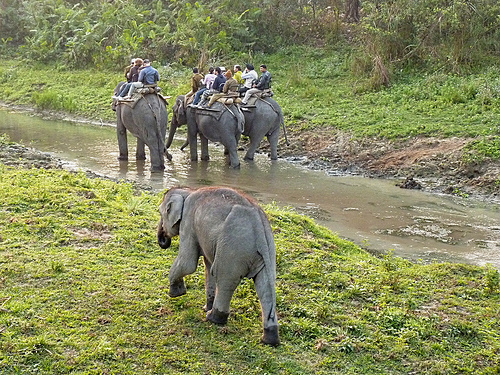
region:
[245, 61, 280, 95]
man looking at other person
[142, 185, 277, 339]
elephant following the men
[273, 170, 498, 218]
the water is murky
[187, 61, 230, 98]
four men riding the elephant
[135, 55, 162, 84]
man has on blue jacket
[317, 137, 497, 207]
rocks on the side of water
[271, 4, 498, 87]
dense bushes in background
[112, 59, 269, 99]
ten men riding three elephants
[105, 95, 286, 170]
three elephants carrying men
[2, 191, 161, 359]
the grass is patchy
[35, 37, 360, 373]
A group of people riding elephants and one lone elephant.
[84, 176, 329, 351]
An elephant by itself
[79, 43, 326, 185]
Three elephants being ridden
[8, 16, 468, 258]
Elephants being ridden down a small stream.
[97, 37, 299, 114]
11 people riding elephants.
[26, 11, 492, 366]
A lush looking landscape with a small river.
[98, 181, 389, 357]
An elephant walking through grass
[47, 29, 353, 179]
Elephants walking on a small river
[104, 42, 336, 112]
Groups of people riding elephants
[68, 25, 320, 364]
Four elephants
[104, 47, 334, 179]
tourists riding elephants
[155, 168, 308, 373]
a baby elephant following behind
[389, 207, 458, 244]
a patch of sand and rocks in the stream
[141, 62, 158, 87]
a man wearing a denim shirt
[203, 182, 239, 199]
fine brown hair on the back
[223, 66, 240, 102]
a man wearing a brown knit cap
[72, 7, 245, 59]
tropical plants next to the stream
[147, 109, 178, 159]
the long gray tail of an elephant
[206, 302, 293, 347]
wet feet on the elephant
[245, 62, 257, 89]
a man wearing a black turban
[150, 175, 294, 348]
a small grey elephant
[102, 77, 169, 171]
a large grey elephant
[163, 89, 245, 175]
a large grey elephant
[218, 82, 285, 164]
a large grey elephant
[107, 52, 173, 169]
people riding on top of an elephant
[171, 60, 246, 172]
people riding on top of an elephant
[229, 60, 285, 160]
people riding on top of an elephant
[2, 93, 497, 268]
a small muddy stream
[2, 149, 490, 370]
a grassy shore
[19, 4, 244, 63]
large green bushes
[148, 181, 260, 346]
this is an elephant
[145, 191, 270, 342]
the elephant is grey in color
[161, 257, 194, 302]
the leg is raised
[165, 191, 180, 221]
the ear is folded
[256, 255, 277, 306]
the tail is long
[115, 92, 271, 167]
the elephants are three in number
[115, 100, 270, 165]
they are in water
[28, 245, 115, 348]
the grass is green in color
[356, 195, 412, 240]
the water is dirty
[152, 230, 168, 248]
the trunk is coiled